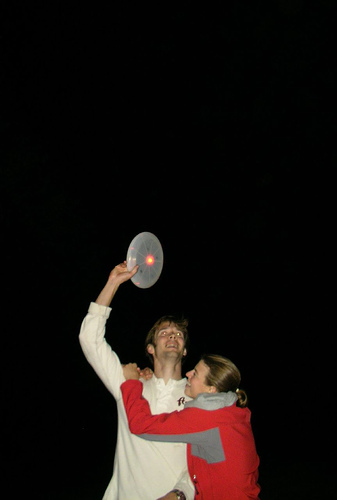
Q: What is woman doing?
A: Hugging man.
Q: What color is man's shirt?
A: White.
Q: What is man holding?
A: Frisbee.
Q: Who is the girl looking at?
A: The man.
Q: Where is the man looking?
A: Up.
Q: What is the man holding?
A: Frisbee.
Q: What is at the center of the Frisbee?
A: A light.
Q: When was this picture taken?
A: Night.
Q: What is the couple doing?
A: Hugging.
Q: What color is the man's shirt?
A: White.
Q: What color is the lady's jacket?
A: Red and grey.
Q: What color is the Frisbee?
A: White/clear.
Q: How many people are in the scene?
A: Two.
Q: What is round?
A: A frisbee.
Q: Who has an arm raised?
A: The man.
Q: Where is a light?
A: On the frisbee.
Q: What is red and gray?
A: Woman's coat.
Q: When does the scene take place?
A: Night.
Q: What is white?
A: Man's shirt.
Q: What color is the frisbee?
A: White.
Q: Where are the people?
A: Outside playing.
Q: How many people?
A: 2.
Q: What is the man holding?
A: Frisbee.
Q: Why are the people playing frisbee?
A: Amusement.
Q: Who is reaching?
A: Woman.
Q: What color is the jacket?
A: Red.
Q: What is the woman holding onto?
A: The man.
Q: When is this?
A: Night.